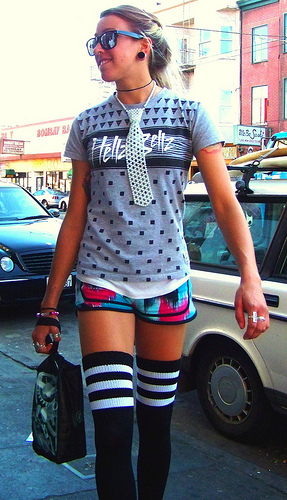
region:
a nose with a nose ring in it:
[93, 40, 105, 55]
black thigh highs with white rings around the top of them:
[79, 350, 179, 498]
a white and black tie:
[112, 79, 157, 206]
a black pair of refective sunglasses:
[86, 29, 144, 56]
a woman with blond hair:
[30, 4, 270, 497]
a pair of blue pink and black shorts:
[74, 274, 196, 324]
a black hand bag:
[31, 314, 85, 464]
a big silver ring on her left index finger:
[247, 310, 265, 323]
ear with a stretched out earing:
[138, 35, 149, 62]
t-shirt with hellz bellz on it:
[64, 90, 227, 302]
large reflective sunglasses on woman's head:
[82, 18, 140, 59]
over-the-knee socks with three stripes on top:
[71, 347, 191, 485]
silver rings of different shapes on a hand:
[232, 293, 275, 335]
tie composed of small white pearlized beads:
[100, 90, 158, 208]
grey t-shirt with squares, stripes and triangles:
[77, 97, 207, 284]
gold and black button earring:
[129, 34, 147, 62]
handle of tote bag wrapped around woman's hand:
[27, 313, 82, 449]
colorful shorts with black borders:
[66, 277, 202, 324]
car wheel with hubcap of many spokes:
[198, 329, 257, 437]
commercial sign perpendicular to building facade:
[232, 98, 265, 152]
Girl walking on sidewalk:
[31, 2, 279, 498]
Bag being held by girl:
[27, 334, 89, 473]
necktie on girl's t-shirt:
[106, 91, 179, 210]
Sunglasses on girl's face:
[71, 22, 168, 62]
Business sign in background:
[227, 118, 271, 152]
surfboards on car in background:
[226, 139, 285, 175]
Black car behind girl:
[8, 184, 71, 319]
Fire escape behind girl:
[172, 32, 215, 88]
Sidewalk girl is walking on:
[2, 446, 234, 496]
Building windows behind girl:
[245, 23, 275, 124]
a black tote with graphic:
[29, 313, 88, 465]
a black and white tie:
[125, 108, 154, 202]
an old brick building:
[234, 1, 286, 121]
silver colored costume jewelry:
[247, 309, 267, 338]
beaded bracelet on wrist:
[33, 304, 61, 317]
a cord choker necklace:
[113, 82, 158, 94]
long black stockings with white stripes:
[81, 344, 172, 498]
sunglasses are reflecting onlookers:
[84, 27, 157, 54]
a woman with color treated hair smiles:
[47, 4, 213, 131]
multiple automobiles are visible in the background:
[7, 178, 56, 230]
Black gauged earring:
[133, 48, 152, 65]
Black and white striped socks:
[77, 352, 182, 494]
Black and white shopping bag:
[29, 345, 88, 463]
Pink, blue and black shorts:
[69, 275, 211, 330]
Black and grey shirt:
[94, 177, 178, 276]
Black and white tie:
[121, 103, 167, 219]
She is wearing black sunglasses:
[80, 23, 159, 55]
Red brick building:
[237, 1, 284, 122]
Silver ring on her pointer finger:
[243, 307, 268, 330]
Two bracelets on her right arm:
[33, 301, 69, 322]